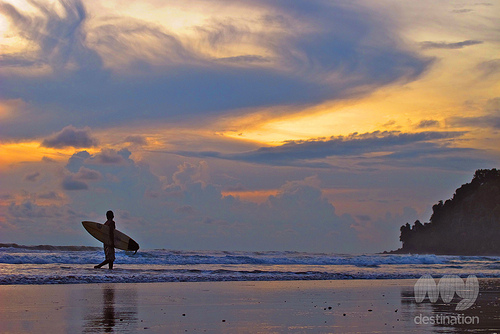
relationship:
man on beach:
[80, 199, 132, 265] [163, 283, 293, 318]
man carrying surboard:
[80, 199, 132, 265] [83, 218, 142, 251]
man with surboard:
[80, 199, 132, 265] [83, 218, 142, 251]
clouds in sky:
[112, 18, 260, 89] [187, 5, 396, 70]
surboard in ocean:
[83, 218, 142, 251] [173, 251, 214, 268]